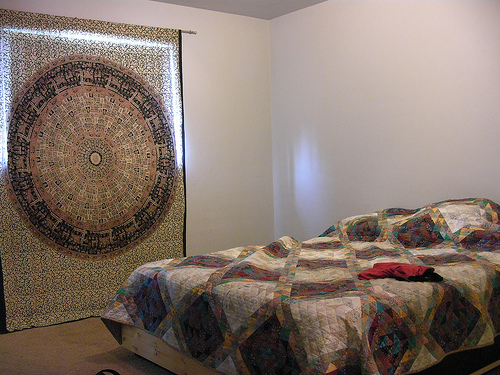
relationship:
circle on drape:
[3, 55, 178, 259] [1, 7, 186, 332]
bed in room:
[109, 199, 497, 374] [2, 3, 498, 372]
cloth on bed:
[358, 261, 445, 283] [191, 258, 489, 331]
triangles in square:
[427, 270, 494, 370] [413, 271, 487, 361]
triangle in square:
[436, 279, 448, 302] [413, 271, 487, 361]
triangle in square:
[427, 278, 438, 316] [413, 271, 487, 361]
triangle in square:
[432, 340, 452, 358] [413, 271, 487, 361]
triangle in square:
[421, 330, 436, 354] [413, 271, 487, 361]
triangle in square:
[424, 301, 440, 324] [413, 271, 487, 361]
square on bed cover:
[413, 271, 487, 361] [100, 198, 499, 375]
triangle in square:
[210, 301, 224, 324] [166, 280, 240, 372]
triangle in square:
[216, 308, 232, 336] [166, 280, 240, 372]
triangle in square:
[172, 299, 189, 315] [166, 280, 240, 372]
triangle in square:
[182, 286, 204, 308] [166, 280, 240, 372]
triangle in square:
[177, 340, 189, 352] [166, 280, 240, 372]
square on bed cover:
[166, 280, 240, 372] [100, 198, 499, 375]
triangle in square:
[126, 299, 138, 322] [114, 270, 177, 341]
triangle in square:
[160, 285, 170, 310] [114, 270, 177, 341]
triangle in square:
[162, 286, 174, 309] [114, 270, 177, 341]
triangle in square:
[164, 314, 178, 330] [114, 270, 177, 341]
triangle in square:
[156, 321, 170, 336] [114, 270, 177, 341]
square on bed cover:
[114, 270, 177, 341] [196, 246, 360, 341]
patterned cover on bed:
[110, 193, 499, 373] [109, 199, 497, 374]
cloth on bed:
[358, 259, 443, 283] [109, 199, 497, 374]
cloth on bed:
[358, 261, 445, 283] [116, 211, 494, 355]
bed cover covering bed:
[100, 198, 499, 375] [109, 199, 497, 374]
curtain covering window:
[4, 29, 194, 320] [0, 31, 171, 206]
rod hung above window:
[177, 27, 200, 45] [10, 7, 219, 251]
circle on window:
[3, 55, 178, 259] [14, 26, 252, 184]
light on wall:
[277, 123, 337, 243] [270, 0, 480, 267]